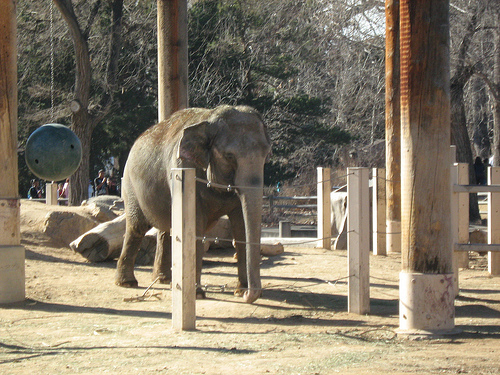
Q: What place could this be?
A: It is a zoo.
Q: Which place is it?
A: It is a zoo.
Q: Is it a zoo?
A: Yes, it is a zoo.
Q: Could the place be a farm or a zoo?
A: It is a zoo.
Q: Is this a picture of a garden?
A: No, the picture is showing a zoo.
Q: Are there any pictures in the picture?
A: No, there are no pictures.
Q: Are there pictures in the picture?
A: No, there are no pictures.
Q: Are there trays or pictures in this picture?
A: No, there are no pictures or trays.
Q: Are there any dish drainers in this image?
A: No, there are no dish drainers.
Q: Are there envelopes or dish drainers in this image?
A: No, there are no dish drainers or envelopes.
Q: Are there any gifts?
A: No, there are no gifts.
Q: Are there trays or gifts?
A: No, there are no gifts or trays.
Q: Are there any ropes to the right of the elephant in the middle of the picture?
A: Yes, there is a rope to the right of the elephant.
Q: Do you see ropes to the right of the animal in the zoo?
A: Yes, there is a rope to the right of the elephant.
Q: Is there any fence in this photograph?
A: Yes, there is a fence.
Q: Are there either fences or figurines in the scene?
A: Yes, there is a fence.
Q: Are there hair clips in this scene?
A: No, there are no hair clips.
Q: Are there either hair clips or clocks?
A: No, there are no hair clips or clocks.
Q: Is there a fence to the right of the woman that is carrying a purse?
A: Yes, there is a fence to the right of the woman.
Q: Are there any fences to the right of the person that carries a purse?
A: Yes, there is a fence to the right of the woman.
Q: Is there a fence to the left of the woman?
A: No, the fence is to the right of the woman.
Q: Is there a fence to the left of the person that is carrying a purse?
A: No, the fence is to the right of the woman.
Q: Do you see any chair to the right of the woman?
A: No, there is a fence to the right of the woman.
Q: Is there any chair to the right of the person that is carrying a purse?
A: No, there is a fence to the right of the woman.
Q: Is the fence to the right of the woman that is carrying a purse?
A: Yes, the fence is to the right of the woman.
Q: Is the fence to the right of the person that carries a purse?
A: Yes, the fence is to the right of the woman.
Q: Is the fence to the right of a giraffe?
A: No, the fence is to the right of the woman.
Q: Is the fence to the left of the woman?
A: No, the fence is to the right of the woman.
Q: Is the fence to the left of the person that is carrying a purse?
A: No, the fence is to the right of the woman.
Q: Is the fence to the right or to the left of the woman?
A: The fence is to the right of the woman.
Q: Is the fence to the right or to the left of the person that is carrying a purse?
A: The fence is to the right of the woman.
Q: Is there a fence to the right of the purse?
A: Yes, there is a fence to the right of the purse.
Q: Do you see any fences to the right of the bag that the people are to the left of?
A: Yes, there is a fence to the right of the purse.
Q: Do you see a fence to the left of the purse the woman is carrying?
A: No, the fence is to the right of the purse.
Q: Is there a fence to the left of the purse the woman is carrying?
A: No, the fence is to the right of the purse.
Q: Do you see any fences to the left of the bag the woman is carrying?
A: No, the fence is to the right of the purse.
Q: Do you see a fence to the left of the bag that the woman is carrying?
A: No, the fence is to the right of the purse.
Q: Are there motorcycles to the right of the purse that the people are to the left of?
A: No, there is a fence to the right of the purse.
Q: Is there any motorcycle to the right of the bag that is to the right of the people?
A: No, there is a fence to the right of the purse.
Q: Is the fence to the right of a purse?
A: Yes, the fence is to the right of a purse.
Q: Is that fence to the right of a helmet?
A: No, the fence is to the right of a purse.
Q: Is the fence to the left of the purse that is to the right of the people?
A: No, the fence is to the right of the purse.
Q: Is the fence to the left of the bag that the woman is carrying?
A: No, the fence is to the right of the purse.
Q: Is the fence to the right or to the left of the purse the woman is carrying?
A: The fence is to the right of the purse.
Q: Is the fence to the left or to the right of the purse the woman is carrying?
A: The fence is to the right of the purse.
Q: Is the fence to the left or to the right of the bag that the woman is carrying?
A: The fence is to the right of the purse.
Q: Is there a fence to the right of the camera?
A: Yes, there is a fence to the right of the camera.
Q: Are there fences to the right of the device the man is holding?
A: Yes, there is a fence to the right of the camera.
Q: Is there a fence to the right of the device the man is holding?
A: Yes, there is a fence to the right of the camera.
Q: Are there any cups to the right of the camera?
A: No, there is a fence to the right of the camera.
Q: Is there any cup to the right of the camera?
A: No, there is a fence to the right of the camera.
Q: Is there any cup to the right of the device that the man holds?
A: No, there is a fence to the right of the camera.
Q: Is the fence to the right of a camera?
A: Yes, the fence is to the right of a camera.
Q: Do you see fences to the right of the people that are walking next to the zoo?
A: Yes, there is a fence to the right of the people.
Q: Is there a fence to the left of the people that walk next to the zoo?
A: No, the fence is to the right of the people.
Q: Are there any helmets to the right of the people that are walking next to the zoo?
A: No, there is a fence to the right of the people.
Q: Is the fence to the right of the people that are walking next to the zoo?
A: Yes, the fence is to the right of the people.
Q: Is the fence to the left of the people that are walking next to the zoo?
A: No, the fence is to the right of the people.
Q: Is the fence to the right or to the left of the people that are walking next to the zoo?
A: The fence is to the right of the people.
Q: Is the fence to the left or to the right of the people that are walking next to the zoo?
A: The fence is to the right of the people.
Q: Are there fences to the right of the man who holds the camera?
A: Yes, there is a fence to the right of the man.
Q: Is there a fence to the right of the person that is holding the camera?
A: Yes, there is a fence to the right of the man.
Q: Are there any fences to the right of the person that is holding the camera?
A: Yes, there is a fence to the right of the man.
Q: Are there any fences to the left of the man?
A: No, the fence is to the right of the man.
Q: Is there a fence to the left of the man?
A: No, the fence is to the right of the man.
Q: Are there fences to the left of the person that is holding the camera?
A: No, the fence is to the right of the man.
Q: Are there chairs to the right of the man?
A: No, there is a fence to the right of the man.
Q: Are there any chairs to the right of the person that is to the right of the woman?
A: No, there is a fence to the right of the man.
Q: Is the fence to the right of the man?
A: Yes, the fence is to the right of the man.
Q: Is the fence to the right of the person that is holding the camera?
A: Yes, the fence is to the right of the man.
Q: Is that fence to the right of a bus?
A: No, the fence is to the right of the man.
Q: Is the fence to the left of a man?
A: No, the fence is to the right of a man.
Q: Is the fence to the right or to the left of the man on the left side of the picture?
A: The fence is to the right of the man.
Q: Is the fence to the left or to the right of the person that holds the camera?
A: The fence is to the right of the man.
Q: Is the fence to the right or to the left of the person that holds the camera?
A: The fence is to the right of the man.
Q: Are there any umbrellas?
A: No, there are no umbrellas.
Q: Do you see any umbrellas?
A: No, there are no umbrellas.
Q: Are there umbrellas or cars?
A: No, there are no umbrellas or cars.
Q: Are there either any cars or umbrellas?
A: No, there are no umbrellas or cars.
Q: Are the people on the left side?
A: Yes, the people are on the left of the image.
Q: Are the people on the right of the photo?
A: No, the people are on the left of the image.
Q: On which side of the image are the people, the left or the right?
A: The people are on the left of the image.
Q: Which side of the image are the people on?
A: The people are on the left of the image.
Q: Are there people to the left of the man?
A: Yes, there are people to the left of the man.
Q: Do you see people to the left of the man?
A: Yes, there are people to the left of the man.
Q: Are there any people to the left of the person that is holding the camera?
A: Yes, there are people to the left of the man.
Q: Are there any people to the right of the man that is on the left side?
A: No, the people are to the left of the man.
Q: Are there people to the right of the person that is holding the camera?
A: No, the people are to the left of the man.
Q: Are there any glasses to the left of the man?
A: No, there are people to the left of the man.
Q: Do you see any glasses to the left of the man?
A: No, there are people to the left of the man.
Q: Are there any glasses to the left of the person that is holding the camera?
A: No, there are people to the left of the man.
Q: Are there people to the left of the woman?
A: Yes, there are people to the left of the woman.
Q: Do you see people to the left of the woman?
A: Yes, there are people to the left of the woman.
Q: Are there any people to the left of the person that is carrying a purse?
A: Yes, there are people to the left of the woman.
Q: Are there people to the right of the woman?
A: No, the people are to the left of the woman.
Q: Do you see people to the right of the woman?
A: No, the people are to the left of the woman.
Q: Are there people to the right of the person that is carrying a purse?
A: No, the people are to the left of the woman.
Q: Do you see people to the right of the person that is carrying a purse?
A: No, the people are to the left of the woman.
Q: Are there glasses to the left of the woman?
A: No, there are people to the left of the woman.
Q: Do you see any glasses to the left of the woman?
A: No, there are people to the left of the woman.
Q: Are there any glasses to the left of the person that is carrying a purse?
A: No, there are people to the left of the woman.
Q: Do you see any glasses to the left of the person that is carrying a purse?
A: No, there are people to the left of the woman.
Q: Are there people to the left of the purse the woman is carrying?
A: Yes, there are people to the left of the purse.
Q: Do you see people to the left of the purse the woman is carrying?
A: Yes, there are people to the left of the purse.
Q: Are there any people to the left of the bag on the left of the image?
A: Yes, there are people to the left of the purse.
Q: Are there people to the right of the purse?
A: No, the people are to the left of the purse.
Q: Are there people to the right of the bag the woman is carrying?
A: No, the people are to the left of the purse.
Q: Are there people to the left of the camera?
A: Yes, there are people to the left of the camera.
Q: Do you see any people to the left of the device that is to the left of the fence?
A: Yes, there are people to the left of the camera.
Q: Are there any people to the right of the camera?
A: No, the people are to the left of the camera.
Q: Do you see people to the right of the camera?
A: No, the people are to the left of the camera.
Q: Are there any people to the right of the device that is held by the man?
A: No, the people are to the left of the camera.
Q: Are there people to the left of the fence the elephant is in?
A: Yes, there are people to the left of the fence.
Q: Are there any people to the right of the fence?
A: No, the people are to the left of the fence.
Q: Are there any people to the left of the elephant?
A: Yes, there are people to the left of the elephant.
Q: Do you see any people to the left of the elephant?
A: Yes, there are people to the left of the elephant.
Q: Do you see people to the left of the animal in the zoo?
A: Yes, there are people to the left of the elephant.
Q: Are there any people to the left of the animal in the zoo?
A: Yes, there are people to the left of the elephant.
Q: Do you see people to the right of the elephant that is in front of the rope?
A: No, the people are to the left of the elephant.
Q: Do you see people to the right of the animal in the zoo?
A: No, the people are to the left of the elephant.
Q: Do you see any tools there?
A: No, there are no tools.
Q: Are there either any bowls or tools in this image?
A: No, there are no tools or bowls.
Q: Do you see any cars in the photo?
A: No, there are no cars.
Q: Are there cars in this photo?
A: No, there are no cars.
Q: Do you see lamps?
A: No, there are no lamps.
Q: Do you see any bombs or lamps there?
A: No, there are no lamps or bombs.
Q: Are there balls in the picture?
A: Yes, there is a ball.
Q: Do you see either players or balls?
A: Yes, there is a ball.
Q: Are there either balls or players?
A: Yes, there is a ball.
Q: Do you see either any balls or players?
A: Yes, there is a ball.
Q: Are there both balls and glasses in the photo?
A: No, there is a ball but no glasses.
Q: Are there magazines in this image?
A: No, there are no magazines.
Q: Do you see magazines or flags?
A: No, there are no magazines or flags.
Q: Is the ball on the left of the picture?
A: Yes, the ball is on the left of the image.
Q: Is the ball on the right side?
A: No, the ball is on the left of the image.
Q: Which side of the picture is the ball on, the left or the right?
A: The ball is on the left of the image.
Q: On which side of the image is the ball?
A: The ball is on the left of the image.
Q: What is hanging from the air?
A: The ball is hanging from the air.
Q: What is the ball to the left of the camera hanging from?
A: The ball is hanging from the air.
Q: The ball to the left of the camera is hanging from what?
A: The ball is hanging from the air.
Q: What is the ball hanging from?
A: The ball is hanging from the air.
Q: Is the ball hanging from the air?
A: Yes, the ball is hanging from the air.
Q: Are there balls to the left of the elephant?
A: Yes, there is a ball to the left of the elephant.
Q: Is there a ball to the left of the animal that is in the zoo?
A: Yes, there is a ball to the left of the elephant.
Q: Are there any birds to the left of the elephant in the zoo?
A: No, there is a ball to the left of the elephant.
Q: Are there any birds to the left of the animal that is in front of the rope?
A: No, there is a ball to the left of the elephant.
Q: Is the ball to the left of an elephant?
A: Yes, the ball is to the left of an elephant.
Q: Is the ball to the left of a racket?
A: No, the ball is to the left of an elephant.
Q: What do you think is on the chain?
A: The ball is on the chain.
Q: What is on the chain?
A: The ball is on the chain.